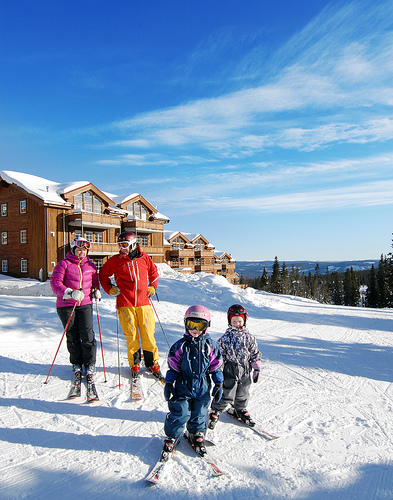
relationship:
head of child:
[182, 303, 212, 334] [162, 301, 224, 454]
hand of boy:
[252, 359, 263, 383] [212, 304, 263, 429]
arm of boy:
[247, 332, 262, 383] [212, 304, 263, 429]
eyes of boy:
[232, 318, 243, 325] [215, 303, 265, 434]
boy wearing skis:
[209, 304, 261, 420] [207, 418, 277, 439]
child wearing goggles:
[152, 300, 220, 457] [184, 315, 213, 331]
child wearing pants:
[152, 300, 220, 457] [167, 379, 217, 426]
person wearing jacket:
[163, 304, 223, 457] [166, 331, 224, 383]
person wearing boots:
[221, 299, 256, 415] [211, 384, 256, 428]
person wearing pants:
[213, 299, 260, 415] [221, 364, 252, 413]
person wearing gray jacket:
[163, 304, 223, 457] [216, 322, 263, 363]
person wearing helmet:
[213, 299, 260, 415] [225, 303, 248, 324]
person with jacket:
[51, 234, 102, 379] [98, 253, 159, 305]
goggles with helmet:
[224, 303, 251, 317] [110, 217, 141, 269]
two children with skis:
[144, 303, 278, 484] [135, 420, 233, 489]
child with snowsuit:
[152, 300, 220, 457] [156, 326, 226, 453]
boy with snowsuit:
[209, 304, 261, 420] [209, 324, 259, 415]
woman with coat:
[50, 238, 108, 388] [46, 250, 104, 314]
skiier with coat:
[96, 222, 179, 384] [100, 247, 158, 314]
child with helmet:
[152, 300, 220, 457] [180, 298, 214, 337]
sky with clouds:
[0, 0, 392, 259] [0, 0, 392, 261]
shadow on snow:
[239, 329, 391, 386] [1, 262, 391, 498]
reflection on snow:
[0, 426, 199, 487] [1, 262, 391, 498]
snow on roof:
[2, 165, 90, 209] [2, 167, 170, 223]